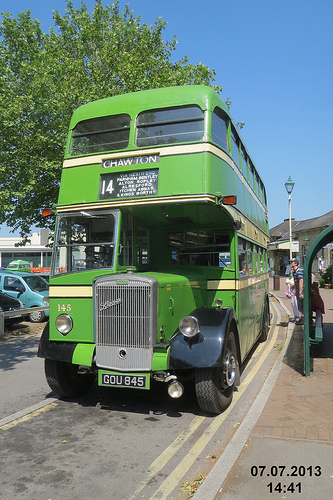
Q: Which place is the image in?
A: It is at the street.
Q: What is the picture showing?
A: It is showing a street.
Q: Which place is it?
A: It is a street.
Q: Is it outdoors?
A: Yes, it is outdoors.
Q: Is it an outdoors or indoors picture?
A: It is outdoors.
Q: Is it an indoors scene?
A: No, it is outdoors.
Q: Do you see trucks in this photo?
A: No, there are no trucks.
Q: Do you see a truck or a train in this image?
A: No, there are no trucks or trains.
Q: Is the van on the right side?
A: No, the van is on the left of the image.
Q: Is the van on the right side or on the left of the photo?
A: The van is on the left of the image.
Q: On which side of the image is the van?
A: The van is on the left of the image.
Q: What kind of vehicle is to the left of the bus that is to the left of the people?
A: The vehicle is a van.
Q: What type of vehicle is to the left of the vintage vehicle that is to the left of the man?
A: The vehicle is a van.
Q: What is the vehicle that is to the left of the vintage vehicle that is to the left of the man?
A: The vehicle is a van.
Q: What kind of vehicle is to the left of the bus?
A: The vehicle is a van.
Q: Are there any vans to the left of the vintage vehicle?
A: Yes, there is a van to the left of the bus.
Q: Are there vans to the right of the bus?
A: No, the van is to the left of the bus.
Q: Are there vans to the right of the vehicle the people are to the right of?
A: No, the van is to the left of the bus.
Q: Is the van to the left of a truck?
A: No, the van is to the left of the bus.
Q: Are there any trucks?
A: No, there are no trucks.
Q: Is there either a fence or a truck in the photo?
A: No, there are no trucks or fences.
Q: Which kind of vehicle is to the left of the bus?
A: The vehicle is a car.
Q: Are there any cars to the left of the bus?
A: Yes, there is a car to the left of the bus.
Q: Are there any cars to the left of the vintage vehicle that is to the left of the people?
A: Yes, there is a car to the left of the bus.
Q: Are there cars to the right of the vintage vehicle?
A: No, the car is to the left of the bus.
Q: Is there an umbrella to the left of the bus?
A: No, there is a car to the left of the bus.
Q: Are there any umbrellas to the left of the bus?
A: No, there is a car to the left of the bus.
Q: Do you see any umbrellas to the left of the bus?
A: No, there is a car to the left of the bus.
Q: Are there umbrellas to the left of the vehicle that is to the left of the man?
A: No, there is a car to the left of the bus.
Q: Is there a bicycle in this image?
A: No, there are no bicycles.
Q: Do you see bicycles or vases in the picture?
A: No, there are no bicycles or vases.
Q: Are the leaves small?
A: Yes, the leaves are small.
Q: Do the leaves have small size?
A: Yes, the leaves are small.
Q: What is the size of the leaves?
A: The leaves are small.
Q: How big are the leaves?
A: The leaves are small.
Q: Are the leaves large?
A: No, the leaves are small.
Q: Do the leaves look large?
A: No, the leaves are small.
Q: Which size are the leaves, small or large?
A: The leaves are small.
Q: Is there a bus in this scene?
A: Yes, there is a bus.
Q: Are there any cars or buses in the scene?
A: Yes, there is a bus.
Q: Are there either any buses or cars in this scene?
A: Yes, there is a bus.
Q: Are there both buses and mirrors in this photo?
A: No, there is a bus but no mirrors.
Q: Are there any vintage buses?
A: Yes, there is a vintage bus.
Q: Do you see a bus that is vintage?
A: Yes, there is a bus that is vintage.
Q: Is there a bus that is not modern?
A: Yes, there is a vintage bus.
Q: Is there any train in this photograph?
A: No, there are no trains.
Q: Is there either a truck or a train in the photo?
A: No, there are no trains or trucks.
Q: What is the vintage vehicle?
A: The vehicle is a bus.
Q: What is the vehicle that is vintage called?
A: The vehicle is a bus.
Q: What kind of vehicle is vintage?
A: The vehicle is a bus.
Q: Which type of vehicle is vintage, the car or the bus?
A: The bus is vintage.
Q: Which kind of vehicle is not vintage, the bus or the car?
A: The car is not vintage.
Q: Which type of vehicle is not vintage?
A: The vehicle is a car.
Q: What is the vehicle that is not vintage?
A: The vehicle is a car.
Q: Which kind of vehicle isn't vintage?
A: The vehicle is a car.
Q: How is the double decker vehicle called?
A: The vehicle is a bus.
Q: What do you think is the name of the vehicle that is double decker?
A: The vehicle is a bus.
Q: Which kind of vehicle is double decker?
A: The vehicle is a bus.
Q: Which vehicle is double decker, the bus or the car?
A: The bus is double decker.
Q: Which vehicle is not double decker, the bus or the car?
A: The car is not double decker.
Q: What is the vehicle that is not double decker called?
A: The vehicle is a car.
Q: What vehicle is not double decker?
A: The vehicle is a car.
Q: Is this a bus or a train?
A: This is a bus.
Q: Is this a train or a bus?
A: This is a bus.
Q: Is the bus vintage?
A: Yes, the bus is vintage.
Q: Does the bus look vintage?
A: Yes, the bus is vintage.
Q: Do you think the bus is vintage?
A: Yes, the bus is vintage.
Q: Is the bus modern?
A: No, the bus is vintage.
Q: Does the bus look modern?
A: No, the bus is vintage.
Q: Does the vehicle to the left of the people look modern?
A: No, the bus is vintage.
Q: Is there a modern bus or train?
A: No, there is a bus but it is vintage.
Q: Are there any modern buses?
A: No, there is a bus but it is vintage.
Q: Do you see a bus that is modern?
A: No, there is a bus but it is vintage.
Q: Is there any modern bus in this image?
A: No, there is a bus but it is vintage.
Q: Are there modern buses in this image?
A: No, there is a bus but it is vintage.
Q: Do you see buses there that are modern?
A: No, there is a bus but it is vintage.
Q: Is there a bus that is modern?
A: No, there is a bus but it is vintage.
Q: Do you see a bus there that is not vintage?
A: No, there is a bus but it is vintage.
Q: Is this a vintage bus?
A: Yes, this is a vintage bus.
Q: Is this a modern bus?
A: No, this is a vintage bus.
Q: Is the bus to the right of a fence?
A: No, the bus is to the right of the car.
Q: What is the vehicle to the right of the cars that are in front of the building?
A: The vehicle is a bus.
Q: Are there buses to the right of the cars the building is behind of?
A: Yes, there is a bus to the right of the cars.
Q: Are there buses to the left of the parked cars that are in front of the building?
A: No, the bus is to the right of the cars.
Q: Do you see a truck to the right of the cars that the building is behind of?
A: No, there is a bus to the right of the cars.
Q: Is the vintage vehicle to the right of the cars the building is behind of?
A: Yes, the bus is to the right of the cars.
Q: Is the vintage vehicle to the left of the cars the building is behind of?
A: No, the bus is to the right of the cars.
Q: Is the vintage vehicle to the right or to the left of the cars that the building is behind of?
A: The bus is to the right of the cars.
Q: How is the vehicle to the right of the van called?
A: The vehicle is a bus.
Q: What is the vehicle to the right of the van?
A: The vehicle is a bus.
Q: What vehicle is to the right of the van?
A: The vehicle is a bus.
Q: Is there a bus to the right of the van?
A: Yes, there is a bus to the right of the van.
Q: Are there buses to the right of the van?
A: Yes, there is a bus to the right of the van.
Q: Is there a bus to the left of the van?
A: No, the bus is to the right of the van.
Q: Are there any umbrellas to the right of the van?
A: No, there is a bus to the right of the van.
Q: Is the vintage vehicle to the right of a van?
A: Yes, the bus is to the right of a van.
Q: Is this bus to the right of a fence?
A: No, the bus is to the right of a van.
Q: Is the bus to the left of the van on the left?
A: No, the bus is to the right of the van.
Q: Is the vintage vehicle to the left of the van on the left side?
A: No, the bus is to the right of the van.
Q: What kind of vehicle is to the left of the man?
A: The vehicle is a bus.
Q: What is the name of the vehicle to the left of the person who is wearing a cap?
A: The vehicle is a bus.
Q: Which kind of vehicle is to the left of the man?
A: The vehicle is a bus.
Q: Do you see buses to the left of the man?
A: Yes, there is a bus to the left of the man.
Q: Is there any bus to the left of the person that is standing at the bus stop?
A: Yes, there is a bus to the left of the man.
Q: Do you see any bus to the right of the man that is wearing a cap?
A: No, the bus is to the left of the man.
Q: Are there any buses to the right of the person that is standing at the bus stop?
A: No, the bus is to the left of the man.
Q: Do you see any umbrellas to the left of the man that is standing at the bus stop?
A: No, there is a bus to the left of the man.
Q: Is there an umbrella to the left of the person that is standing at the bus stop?
A: No, there is a bus to the left of the man.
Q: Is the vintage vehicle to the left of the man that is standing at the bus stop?
A: Yes, the bus is to the left of the man.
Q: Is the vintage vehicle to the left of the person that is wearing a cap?
A: Yes, the bus is to the left of the man.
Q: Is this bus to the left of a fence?
A: No, the bus is to the left of the man.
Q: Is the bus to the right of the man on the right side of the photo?
A: No, the bus is to the left of the man.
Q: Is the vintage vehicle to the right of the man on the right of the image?
A: No, the bus is to the left of the man.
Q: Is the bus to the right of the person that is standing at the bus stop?
A: No, the bus is to the left of the man.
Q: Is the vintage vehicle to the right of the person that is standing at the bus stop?
A: No, the bus is to the left of the man.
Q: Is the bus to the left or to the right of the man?
A: The bus is to the left of the man.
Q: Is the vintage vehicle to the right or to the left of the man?
A: The bus is to the left of the man.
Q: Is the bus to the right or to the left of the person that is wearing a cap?
A: The bus is to the left of the man.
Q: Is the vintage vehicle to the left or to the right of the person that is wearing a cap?
A: The bus is to the left of the man.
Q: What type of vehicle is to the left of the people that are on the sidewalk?
A: The vehicle is a bus.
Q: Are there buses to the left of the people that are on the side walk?
A: Yes, there is a bus to the left of the people.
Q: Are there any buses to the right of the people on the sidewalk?
A: No, the bus is to the left of the people.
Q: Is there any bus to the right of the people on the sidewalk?
A: No, the bus is to the left of the people.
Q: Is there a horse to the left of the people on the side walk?
A: No, there is a bus to the left of the people.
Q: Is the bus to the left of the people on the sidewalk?
A: Yes, the bus is to the left of the people.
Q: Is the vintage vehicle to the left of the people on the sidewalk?
A: Yes, the bus is to the left of the people.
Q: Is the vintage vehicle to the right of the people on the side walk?
A: No, the bus is to the left of the people.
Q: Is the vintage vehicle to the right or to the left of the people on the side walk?
A: The bus is to the left of the people.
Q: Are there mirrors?
A: No, there are no mirrors.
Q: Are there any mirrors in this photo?
A: No, there are no mirrors.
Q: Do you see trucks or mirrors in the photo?
A: No, there are no mirrors or trucks.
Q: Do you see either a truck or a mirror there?
A: No, there are no mirrors or trucks.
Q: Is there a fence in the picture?
A: No, there are no fences.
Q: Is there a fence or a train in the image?
A: No, there are no fences or trains.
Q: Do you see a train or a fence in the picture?
A: No, there are no fences or trains.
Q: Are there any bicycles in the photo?
A: No, there are no bicycles.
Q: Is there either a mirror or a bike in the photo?
A: No, there are no bikes or mirrors.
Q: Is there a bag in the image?
A: No, there are no bags.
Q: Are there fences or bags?
A: No, there are no bags or fences.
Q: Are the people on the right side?
A: Yes, the people are on the right of the image.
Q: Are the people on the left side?
A: No, the people are on the right of the image.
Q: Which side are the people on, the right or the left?
A: The people are on the right of the image.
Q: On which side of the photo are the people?
A: The people are on the right of the image.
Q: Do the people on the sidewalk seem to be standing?
A: Yes, the people are standing.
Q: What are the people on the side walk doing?
A: The people are standing.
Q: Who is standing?
A: The people are standing.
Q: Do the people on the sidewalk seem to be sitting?
A: No, the people are standing.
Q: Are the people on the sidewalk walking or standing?
A: The people are standing.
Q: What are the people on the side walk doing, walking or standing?
A: The people are standing.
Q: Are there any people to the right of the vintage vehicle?
A: Yes, there are people to the right of the bus.